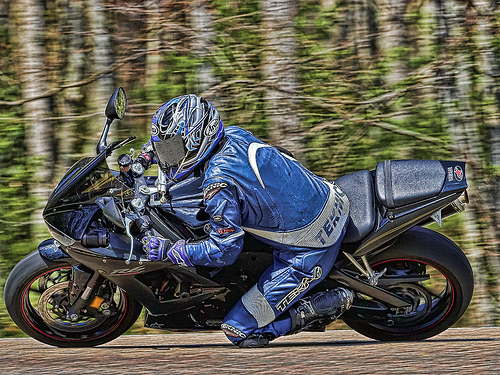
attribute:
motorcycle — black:
[6, 88, 474, 347]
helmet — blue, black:
[152, 92, 226, 188]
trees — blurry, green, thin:
[2, 0, 499, 321]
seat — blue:
[333, 161, 465, 245]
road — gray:
[0, 327, 499, 373]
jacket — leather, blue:
[169, 128, 349, 248]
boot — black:
[290, 288, 351, 332]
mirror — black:
[109, 86, 127, 119]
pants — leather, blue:
[221, 233, 350, 347]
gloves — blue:
[144, 237, 188, 265]